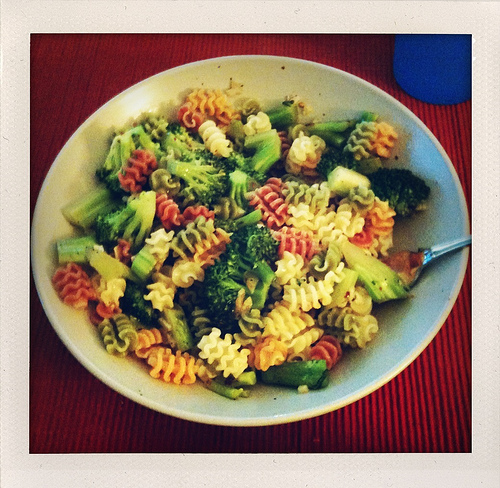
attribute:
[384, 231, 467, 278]
fork — silver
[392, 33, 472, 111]
blue cup — dark blue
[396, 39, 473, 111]
cup — blue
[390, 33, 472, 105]
cup — blue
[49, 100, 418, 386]
noodle — red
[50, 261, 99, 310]
pasta — orange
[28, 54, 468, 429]
bowl — round, white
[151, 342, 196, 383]
pasta — mixed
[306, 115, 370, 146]
broccoli — chunks, several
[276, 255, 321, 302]
pasta — multicolored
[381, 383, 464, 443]
placement — striped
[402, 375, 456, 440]
stripes — red